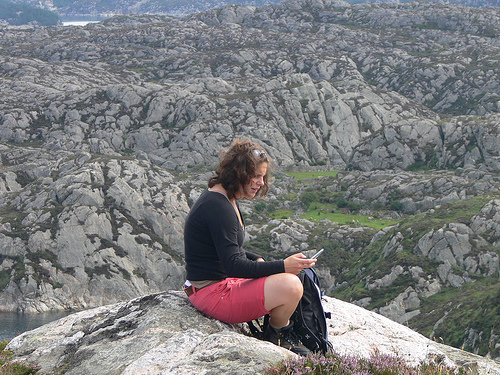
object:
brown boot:
[263, 317, 312, 357]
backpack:
[246, 266, 334, 358]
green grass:
[270, 164, 397, 227]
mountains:
[1, 0, 500, 375]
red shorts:
[183, 277, 273, 325]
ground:
[1, 292, 500, 374]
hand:
[283, 252, 317, 275]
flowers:
[270, 345, 468, 374]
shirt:
[184, 187, 285, 290]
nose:
[256, 178, 265, 186]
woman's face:
[243, 161, 267, 198]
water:
[16, 313, 58, 322]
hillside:
[0, 149, 192, 312]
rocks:
[2, 0, 499, 316]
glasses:
[249, 149, 266, 159]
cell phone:
[310, 248, 325, 259]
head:
[219, 140, 268, 199]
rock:
[3, 289, 498, 374]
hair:
[208, 140, 270, 201]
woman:
[182, 138, 318, 357]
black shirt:
[183, 188, 286, 282]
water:
[61, 21, 87, 26]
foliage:
[282, 163, 499, 335]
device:
[310, 248, 324, 259]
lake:
[0, 313, 42, 341]